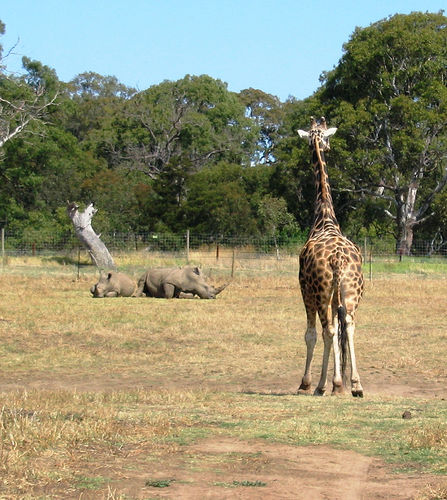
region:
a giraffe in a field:
[288, 113, 369, 401]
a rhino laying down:
[88, 267, 134, 295]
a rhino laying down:
[136, 266, 227, 300]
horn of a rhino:
[215, 277, 233, 293]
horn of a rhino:
[90, 283, 98, 296]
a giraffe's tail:
[332, 258, 347, 378]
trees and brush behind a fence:
[0, 21, 446, 261]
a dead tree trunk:
[67, 198, 116, 265]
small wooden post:
[0, 226, 7, 261]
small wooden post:
[184, 230, 190, 263]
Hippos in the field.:
[76, 256, 224, 335]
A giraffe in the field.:
[300, 111, 378, 426]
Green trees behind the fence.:
[82, 111, 278, 229]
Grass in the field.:
[269, 376, 406, 456]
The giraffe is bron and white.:
[292, 128, 357, 366]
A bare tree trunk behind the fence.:
[60, 198, 123, 273]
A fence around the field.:
[31, 216, 384, 285]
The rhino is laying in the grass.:
[88, 263, 225, 302]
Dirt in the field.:
[59, 352, 248, 409]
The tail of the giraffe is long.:
[329, 253, 358, 341]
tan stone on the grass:
[398, 401, 436, 426]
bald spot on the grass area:
[191, 432, 360, 498]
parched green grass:
[243, 398, 346, 431]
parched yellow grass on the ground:
[45, 413, 121, 451]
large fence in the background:
[118, 218, 276, 261]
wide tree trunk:
[374, 180, 429, 251]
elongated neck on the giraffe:
[282, 105, 356, 204]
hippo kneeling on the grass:
[135, 261, 239, 306]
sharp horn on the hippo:
[206, 277, 232, 294]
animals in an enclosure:
[30, 111, 390, 394]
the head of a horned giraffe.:
[292, 108, 337, 159]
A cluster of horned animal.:
[87, 242, 230, 317]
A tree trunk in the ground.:
[56, 197, 124, 276]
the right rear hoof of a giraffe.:
[345, 378, 363, 402]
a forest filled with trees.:
[0, 9, 446, 262]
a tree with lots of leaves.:
[377, 128, 442, 262]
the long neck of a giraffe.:
[308, 142, 350, 226]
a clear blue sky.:
[0, 0, 443, 100]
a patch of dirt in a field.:
[4, 363, 445, 405]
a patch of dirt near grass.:
[181, 437, 444, 497]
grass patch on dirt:
[246, 385, 380, 462]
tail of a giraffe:
[304, 232, 390, 359]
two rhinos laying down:
[73, 255, 243, 334]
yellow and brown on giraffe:
[303, 248, 335, 296]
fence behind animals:
[157, 220, 270, 261]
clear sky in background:
[126, 21, 269, 59]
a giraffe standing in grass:
[280, 106, 428, 455]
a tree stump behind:
[53, 191, 129, 273]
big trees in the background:
[90, 94, 198, 187]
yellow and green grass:
[113, 391, 250, 459]